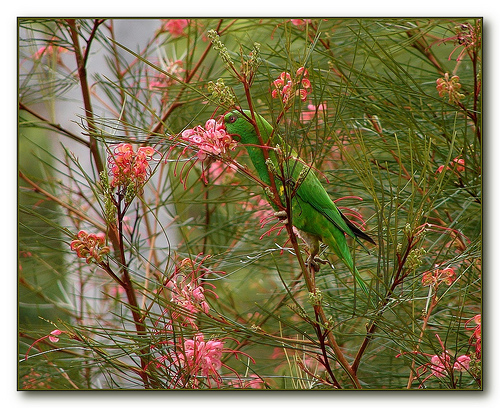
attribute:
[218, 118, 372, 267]
bird — parrot, long, green, camouflaged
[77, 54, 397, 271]
flowers — pink, growing, curling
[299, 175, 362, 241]
feathers — green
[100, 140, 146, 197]
flower — pink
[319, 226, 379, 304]
feather — black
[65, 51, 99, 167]
stick — brown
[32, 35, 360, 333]
tree — bloom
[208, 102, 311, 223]
parrot — green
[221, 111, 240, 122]
eye — open, red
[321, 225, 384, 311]
tail — green, long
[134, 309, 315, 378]
leaves — long, thin, green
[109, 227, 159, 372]
stem — thin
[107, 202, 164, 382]
branches — red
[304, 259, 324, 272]
claws — curled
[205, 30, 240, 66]
buds — green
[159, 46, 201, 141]
branch — long